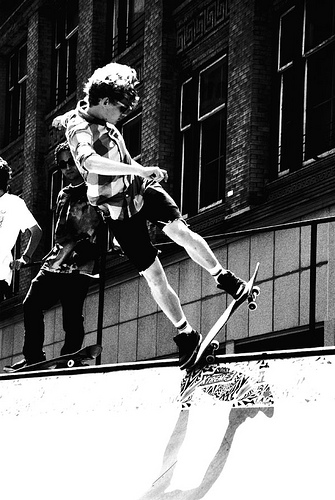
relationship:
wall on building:
[8, 8, 332, 231] [2, 0, 334, 352]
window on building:
[179, 52, 228, 220] [2, 0, 334, 352]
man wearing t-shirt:
[1, 157, 40, 306] [1, 192, 34, 286]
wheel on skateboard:
[248, 301, 257, 311] [184, 262, 262, 372]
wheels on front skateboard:
[247, 283, 259, 312] [184, 262, 262, 372]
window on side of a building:
[266, 1, 334, 178] [2, 0, 334, 352]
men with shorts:
[61, 59, 249, 372] [98, 162, 199, 270]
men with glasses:
[61, 59, 249, 372] [103, 89, 147, 120]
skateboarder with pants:
[4, 142, 103, 370] [22, 268, 85, 364]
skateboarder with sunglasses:
[4, 142, 103, 370] [55, 158, 75, 168]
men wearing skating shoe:
[61, 59, 249, 372] [168, 323, 200, 375]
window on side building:
[175, 55, 229, 218] [2, 0, 334, 352]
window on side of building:
[179, 75, 198, 130] [2, 0, 334, 352]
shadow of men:
[144, 360, 275, 497] [61, 59, 249, 372]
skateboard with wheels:
[184, 262, 262, 372] [208, 338, 219, 349]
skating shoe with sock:
[168, 323, 201, 368] [170, 312, 197, 337]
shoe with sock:
[206, 267, 251, 304] [207, 259, 226, 279]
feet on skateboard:
[166, 262, 249, 369] [177, 256, 268, 381]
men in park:
[61, 59, 249, 372] [2, 2, 330, 326]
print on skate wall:
[174, 361, 273, 404] [1, 346, 333, 499]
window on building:
[198, 55, 229, 120] [2, 0, 334, 352]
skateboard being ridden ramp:
[5, 340, 105, 371] [2, 362, 320, 498]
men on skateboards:
[21, 63, 241, 363] [9, 260, 277, 359]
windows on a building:
[136, 56, 243, 209] [7, 10, 323, 264]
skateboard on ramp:
[177, 256, 268, 381] [3, 337, 334, 496]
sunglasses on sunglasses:
[117, 99, 128, 113] [58, 155, 75, 170]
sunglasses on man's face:
[117, 99, 128, 113] [104, 98, 132, 129]